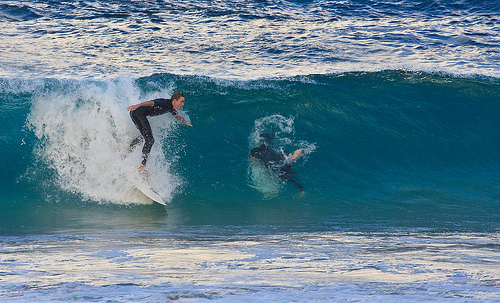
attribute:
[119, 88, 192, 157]
surfer — bent over, bare foot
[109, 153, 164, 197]
surfboard — white